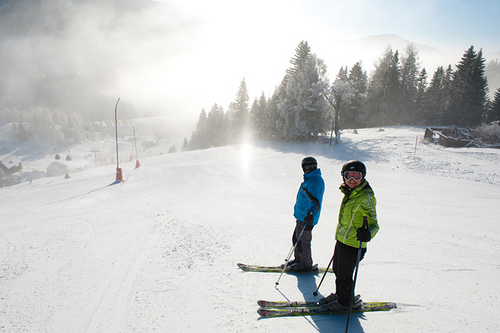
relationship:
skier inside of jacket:
[281, 156, 326, 270] [293, 166, 326, 225]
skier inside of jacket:
[319, 158, 380, 312] [335, 178, 380, 248]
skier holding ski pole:
[281, 156, 326, 270] [274, 209, 314, 288]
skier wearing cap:
[281, 156, 326, 270] [301, 156, 319, 171]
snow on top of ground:
[0, 124, 499, 332] [0, 124, 499, 330]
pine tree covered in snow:
[276, 39, 341, 142] [265, 39, 341, 132]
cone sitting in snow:
[116, 167, 127, 184] [0, 124, 499, 332]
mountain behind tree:
[354, 33, 443, 53] [370, 49, 402, 128]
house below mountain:
[0, 153, 24, 176] [0, 32, 500, 186]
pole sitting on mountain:
[114, 96, 122, 184] [0, 32, 500, 186]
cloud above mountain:
[62, 0, 499, 140] [354, 33, 443, 53]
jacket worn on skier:
[293, 166, 326, 225] [281, 156, 326, 270]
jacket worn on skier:
[335, 178, 380, 248] [319, 158, 380, 312]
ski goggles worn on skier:
[342, 170, 364, 182] [319, 158, 380, 312]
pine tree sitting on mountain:
[276, 39, 341, 142] [0, 32, 500, 186]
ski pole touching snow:
[274, 209, 314, 288] [0, 124, 499, 332]